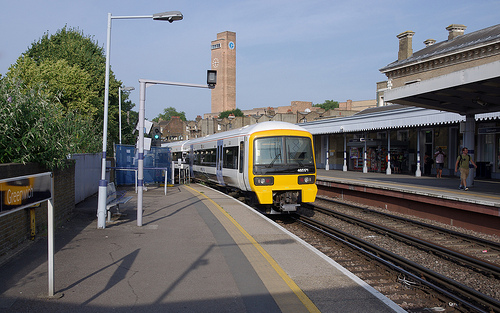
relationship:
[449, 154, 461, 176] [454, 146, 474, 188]
arm of man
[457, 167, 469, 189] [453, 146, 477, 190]
legs of man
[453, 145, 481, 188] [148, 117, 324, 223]
man near train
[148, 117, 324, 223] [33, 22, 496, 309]
train at station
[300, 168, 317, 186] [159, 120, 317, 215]
headlight of train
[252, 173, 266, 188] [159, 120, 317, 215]
headlight of train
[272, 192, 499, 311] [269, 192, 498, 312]
gravel between train tracks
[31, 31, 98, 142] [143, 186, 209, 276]
tree on side of road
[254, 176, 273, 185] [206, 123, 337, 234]
headlight on train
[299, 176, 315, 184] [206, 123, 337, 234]
headlight on train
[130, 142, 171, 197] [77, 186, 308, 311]
fence on road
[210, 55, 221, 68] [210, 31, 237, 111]
clock on building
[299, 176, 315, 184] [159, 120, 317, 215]
headlight on train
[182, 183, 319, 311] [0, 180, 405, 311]
line on concrete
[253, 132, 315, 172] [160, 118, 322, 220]
front windshield on train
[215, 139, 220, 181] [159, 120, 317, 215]
door on train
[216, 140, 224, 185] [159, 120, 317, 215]
door on train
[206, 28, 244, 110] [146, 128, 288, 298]
building behind train station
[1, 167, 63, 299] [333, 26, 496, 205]
sign at station